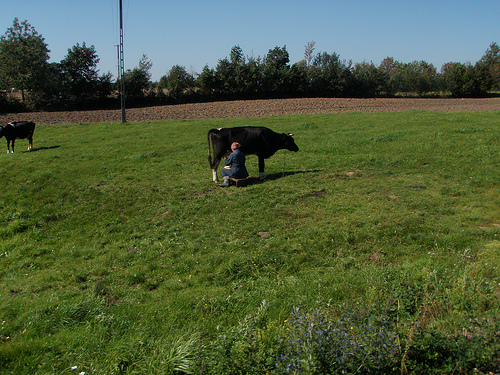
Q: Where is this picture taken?
A: A field.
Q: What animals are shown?
A: Cows.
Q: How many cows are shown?
A: Two.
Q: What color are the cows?
A: Brown.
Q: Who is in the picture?
A: A farmer.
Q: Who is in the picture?
A: A man.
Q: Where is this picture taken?
A: A field.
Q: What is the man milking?
A: A cow.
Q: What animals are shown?
A: Cows.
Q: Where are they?
A: In a field.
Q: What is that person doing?
A: Milking a cow.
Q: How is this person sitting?
A: On a stool.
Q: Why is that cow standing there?
A: To get milked.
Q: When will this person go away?
A: After getting milk.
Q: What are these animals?
A: Cows.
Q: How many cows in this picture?
A: Two cows.